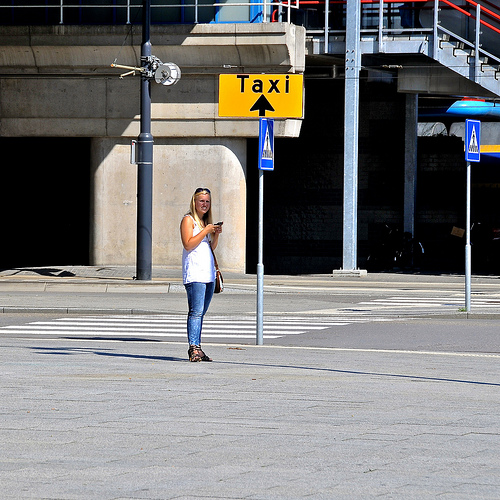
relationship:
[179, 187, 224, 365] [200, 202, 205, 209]
blonde has nose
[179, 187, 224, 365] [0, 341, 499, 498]
blonde standing in concrete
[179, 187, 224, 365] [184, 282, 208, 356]
blonde wearing jean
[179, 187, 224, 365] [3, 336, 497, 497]
blonde standing in sidewalk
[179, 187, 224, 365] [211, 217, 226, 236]
blonde holding phone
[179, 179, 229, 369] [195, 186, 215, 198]
blonde wearing glasses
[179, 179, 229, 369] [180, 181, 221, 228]
blonde has head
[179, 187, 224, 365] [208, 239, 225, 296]
blonde wearing handbag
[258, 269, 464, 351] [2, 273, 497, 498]
marking on street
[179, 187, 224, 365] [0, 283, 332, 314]
blonde standing on sidewalk